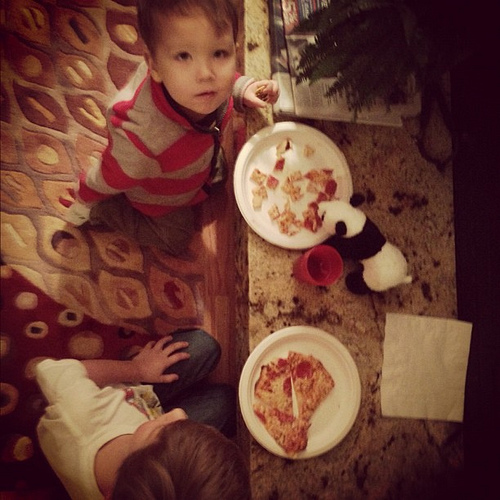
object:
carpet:
[1, 0, 207, 494]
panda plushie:
[312, 196, 414, 297]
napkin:
[373, 311, 474, 425]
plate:
[234, 321, 362, 461]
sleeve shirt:
[31, 355, 151, 498]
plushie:
[378, 269, 393, 283]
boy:
[32, 326, 250, 500]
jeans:
[147, 326, 239, 434]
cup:
[287, 246, 347, 291]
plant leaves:
[340, 65, 355, 79]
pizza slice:
[283, 349, 335, 426]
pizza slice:
[252, 357, 296, 422]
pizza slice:
[248, 400, 312, 462]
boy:
[56, 0, 282, 257]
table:
[233, 1, 470, 498]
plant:
[283, 0, 449, 123]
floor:
[1, 1, 234, 497]